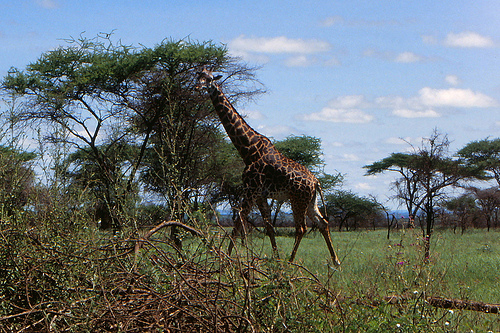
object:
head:
[194, 68, 217, 92]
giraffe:
[198, 67, 344, 272]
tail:
[315, 180, 329, 221]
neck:
[210, 84, 260, 165]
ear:
[212, 72, 224, 81]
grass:
[150, 229, 500, 332]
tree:
[0, 30, 271, 233]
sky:
[0, 2, 500, 198]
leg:
[224, 189, 282, 261]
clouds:
[302, 87, 496, 122]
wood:
[384, 293, 499, 316]